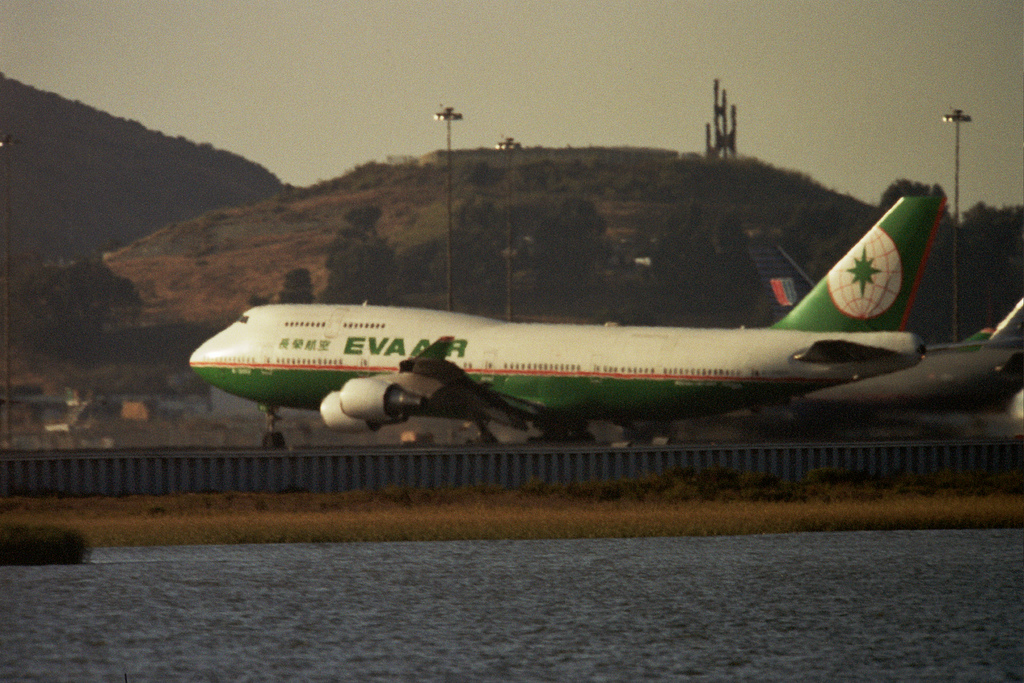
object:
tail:
[767, 194, 950, 332]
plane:
[184, 190, 1022, 441]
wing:
[320, 335, 555, 433]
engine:
[318, 372, 447, 434]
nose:
[187, 320, 252, 385]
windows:
[214, 320, 791, 377]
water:
[0, 521, 1022, 680]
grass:
[0, 465, 1022, 562]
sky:
[0, 0, 1022, 213]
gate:
[0, 434, 1022, 495]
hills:
[63, 136, 959, 349]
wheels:
[258, 415, 690, 449]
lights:
[435, 106, 525, 153]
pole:
[432, 106, 527, 324]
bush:
[2, 522, 95, 566]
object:
[706, 77, 741, 165]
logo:
[824, 224, 904, 321]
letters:
[340, 335, 469, 357]